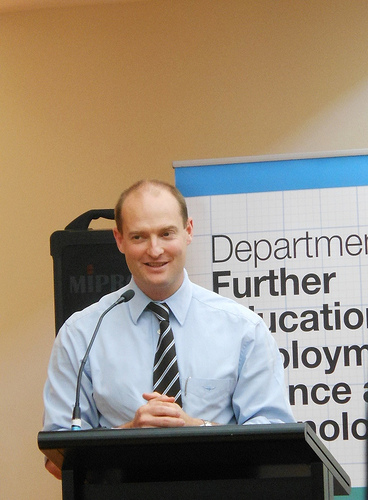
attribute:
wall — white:
[38, 44, 277, 114]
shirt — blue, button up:
[33, 277, 295, 429]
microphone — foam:
[118, 287, 140, 307]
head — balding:
[112, 176, 194, 292]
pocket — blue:
[182, 375, 236, 424]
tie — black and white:
[148, 298, 185, 409]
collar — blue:
[123, 278, 198, 325]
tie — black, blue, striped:
[150, 298, 175, 388]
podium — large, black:
[47, 415, 301, 490]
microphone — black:
[72, 287, 134, 429]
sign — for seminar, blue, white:
[169, 146, 363, 489]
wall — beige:
[2, 3, 366, 499]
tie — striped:
[146, 298, 187, 419]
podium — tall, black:
[36, 420, 353, 497]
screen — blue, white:
[170, 152, 366, 497]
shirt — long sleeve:
[36, 263, 294, 444]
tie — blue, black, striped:
[147, 299, 182, 411]